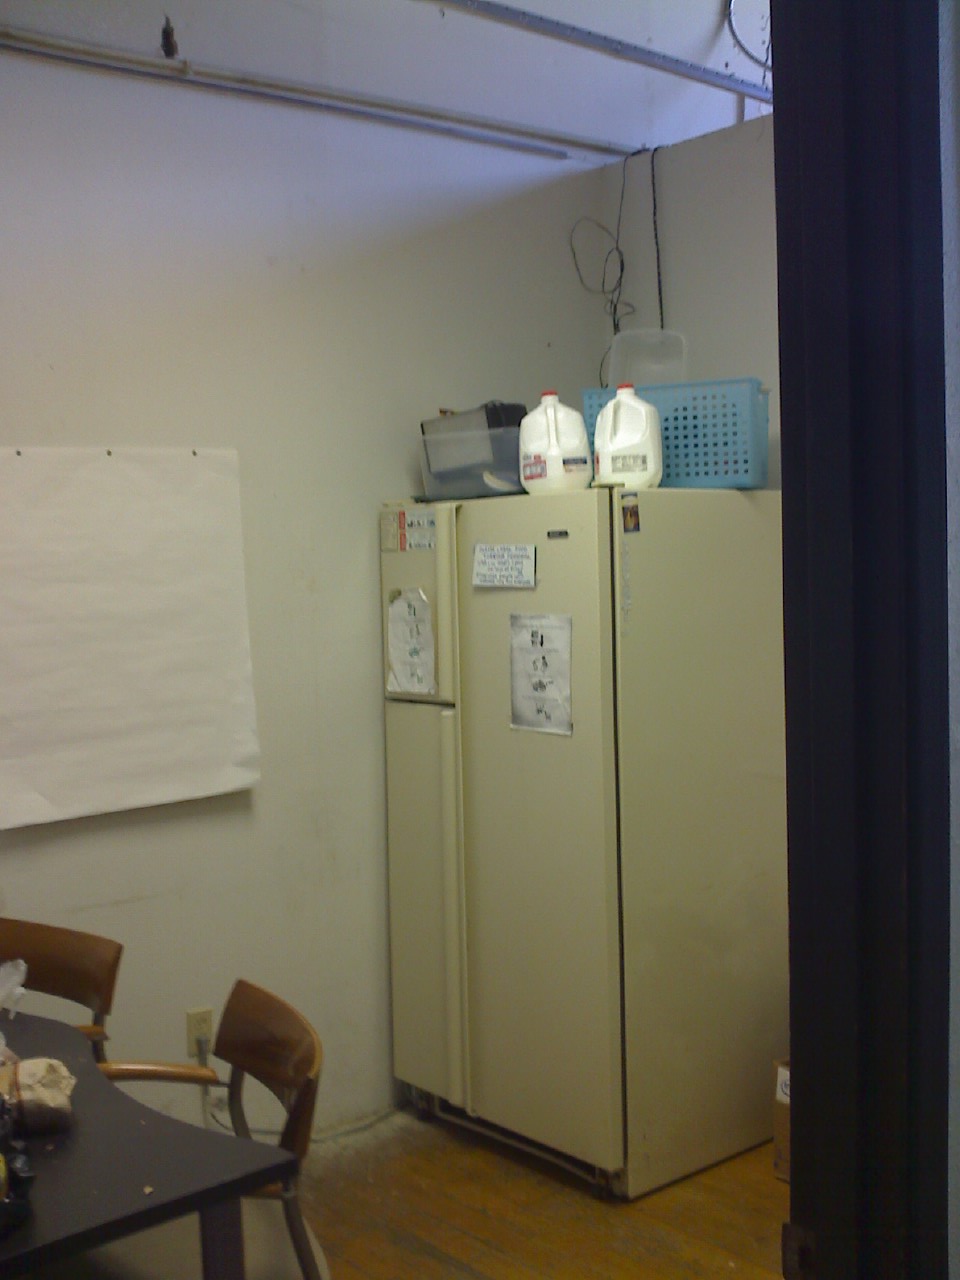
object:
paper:
[473, 544, 537, 589]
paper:
[510, 614, 574, 736]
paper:
[620, 492, 639, 531]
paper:
[399, 510, 437, 551]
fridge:
[377, 486, 789, 1197]